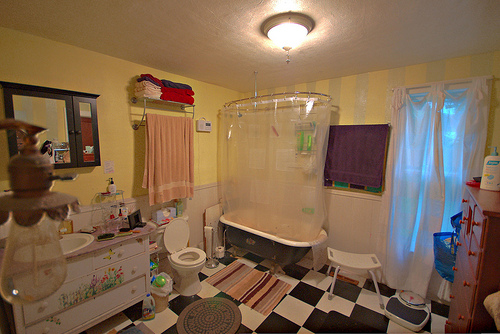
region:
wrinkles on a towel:
[148, 123, 173, 153]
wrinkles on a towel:
[146, 142, 176, 176]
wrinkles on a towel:
[172, 123, 193, 138]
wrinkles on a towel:
[172, 150, 196, 171]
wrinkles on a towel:
[170, 170, 200, 193]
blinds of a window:
[395, 58, 495, 287]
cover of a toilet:
[150, 190, 207, 265]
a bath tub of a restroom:
[215, 188, 332, 280]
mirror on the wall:
[10, 82, 80, 167]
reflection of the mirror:
[42, 94, 60, 120]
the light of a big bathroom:
[251, 22, 310, 59]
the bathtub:
[225, 193, 331, 270]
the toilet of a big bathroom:
[156, 214, 208, 288]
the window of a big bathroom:
[392, 90, 474, 207]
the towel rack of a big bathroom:
[125, 83, 199, 148]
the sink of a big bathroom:
[25, 233, 104, 258]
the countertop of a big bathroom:
[85, 215, 151, 250]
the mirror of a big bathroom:
[15, 81, 117, 168]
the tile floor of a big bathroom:
[259, 278, 348, 331]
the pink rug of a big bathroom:
[220, 259, 277, 319]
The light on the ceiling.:
[261, 17, 310, 58]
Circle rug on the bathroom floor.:
[179, 294, 244, 332]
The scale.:
[385, 283, 426, 330]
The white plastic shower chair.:
[327, 243, 386, 301]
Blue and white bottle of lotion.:
[485, 145, 499, 192]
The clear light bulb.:
[5, 215, 70, 310]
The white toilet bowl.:
[163, 218, 213, 303]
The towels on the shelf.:
[122, 71, 204, 106]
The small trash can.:
[154, 273, 175, 305]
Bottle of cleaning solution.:
[138, 291, 158, 318]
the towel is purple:
[323, 118, 391, 193]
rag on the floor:
[207, 244, 302, 326]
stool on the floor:
[312, 245, 392, 303]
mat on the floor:
[176, 287, 235, 331]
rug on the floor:
[222, 258, 279, 306]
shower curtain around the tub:
[205, 90, 317, 247]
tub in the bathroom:
[217, 215, 323, 270]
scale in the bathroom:
[388, 288, 425, 323]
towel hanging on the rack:
[142, 116, 194, 206]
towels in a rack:
[143, 75, 194, 102]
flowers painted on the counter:
[79, 261, 125, 285]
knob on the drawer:
[465, 248, 480, 260]